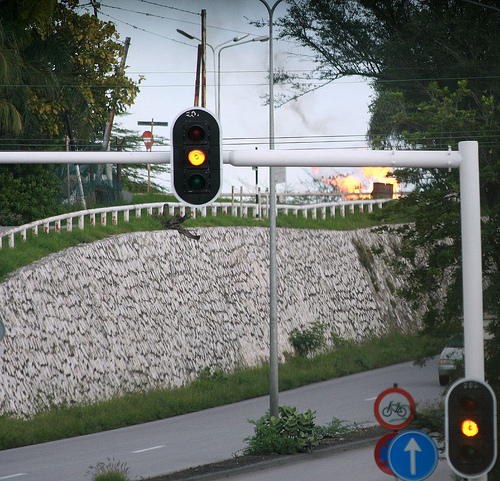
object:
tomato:
[175, 226, 203, 240]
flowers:
[40, 94, 62, 134]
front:
[438, 334, 465, 386]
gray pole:
[261, 0, 281, 420]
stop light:
[443, 378, 497, 480]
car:
[438, 332, 493, 386]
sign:
[374, 433, 399, 476]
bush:
[242, 405, 363, 455]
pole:
[0, 152, 465, 170]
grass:
[54, 405, 108, 432]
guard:
[0, 197, 395, 252]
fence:
[5, 216, 83, 235]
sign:
[387, 429, 438, 481]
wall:
[0, 212, 500, 426]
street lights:
[177, 28, 271, 41]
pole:
[217, 54, 221, 120]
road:
[2, 311, 499, 480]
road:
[0, 221, 82, 232]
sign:
[142, 131, 154, 148]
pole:
[147, 149, 151, 193]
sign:
[374, 387, 416, 430]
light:
[169, 107, 222, 207]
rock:
[109, 291, 226, 361]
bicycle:
[382, 401, 407, 417]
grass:
[293, 355, 338, 374]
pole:
[269, 16, 291, 410]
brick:
[0, 222, 424, 420]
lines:
[129, 444, 166, 454]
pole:
[456, 140, 485, 383]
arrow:
[404, 438, 422, 475]